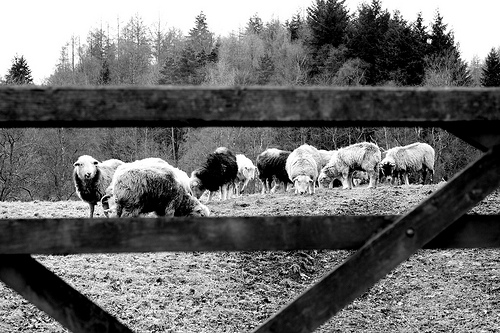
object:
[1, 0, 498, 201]
trees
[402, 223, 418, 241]
bolt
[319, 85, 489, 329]
gate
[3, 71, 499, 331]
fence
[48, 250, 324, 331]
triangle shape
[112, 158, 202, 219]
sheep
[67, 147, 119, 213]
sheep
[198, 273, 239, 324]
grass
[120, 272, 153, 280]
dirt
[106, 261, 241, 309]
ground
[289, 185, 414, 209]
ground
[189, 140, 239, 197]
black sheep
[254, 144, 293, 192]
black sheep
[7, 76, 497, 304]
wood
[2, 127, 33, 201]
leafless tree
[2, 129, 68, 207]
branches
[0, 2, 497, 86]
sky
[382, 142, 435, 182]
sheep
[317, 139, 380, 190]
sheep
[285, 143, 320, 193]
sheep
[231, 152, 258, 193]
sheep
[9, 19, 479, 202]
hill